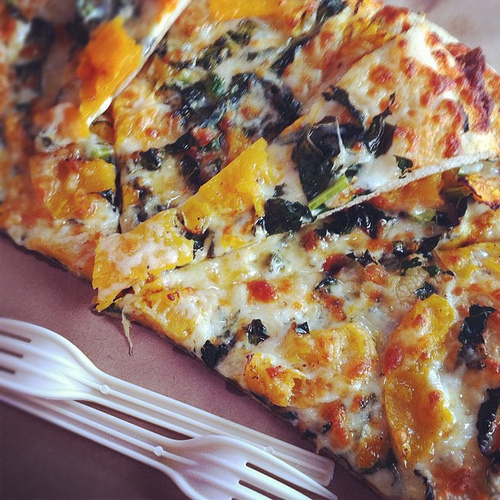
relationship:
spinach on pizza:
[246, 81, 441, 273] [2, 1, 499, 498]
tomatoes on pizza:
[239, 270, 287, 310] [2, 1, 499, 498]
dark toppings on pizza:
[294, 89, 378, 191] [2, 1, 499, 498]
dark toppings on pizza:
[181, 75, 297, 185] [2, 1, 499, 498]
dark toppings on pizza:
[197, 322, 275, 370] [2, 1, 499, 498]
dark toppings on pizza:
[460, 295, 495, 358] [2, 1, 499, 498]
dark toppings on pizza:
[327, 192, 467, 290] [2, 1, 499, 498]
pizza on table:
[0, 0, 500, 500] [4, 252, 271, 497]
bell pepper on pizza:
[168, 121, 300, 229] [69, 43, 450, 370]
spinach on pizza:
[292, 116, 392, 202] [2, 1, 499, 498]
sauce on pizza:
[246, 277, 278, 301] [2, 1, 499, 498]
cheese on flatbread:
[7, 0, 497, 490] [24, 27, 494, 434]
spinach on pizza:
[285, 139, 356, 180] [92, 2, 421, 240]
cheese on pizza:
[143, 237, 330, 356] [2, 1, 499, 498]